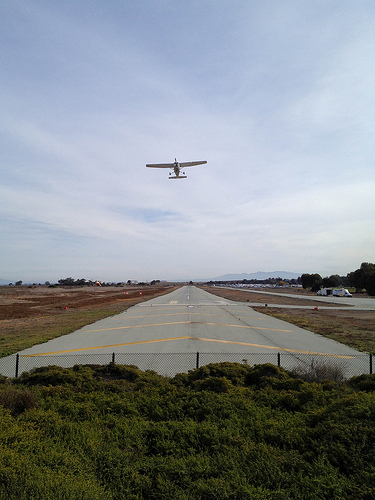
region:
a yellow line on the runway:
[17, 331, 358, 372]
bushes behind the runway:
[3, 363, 373, 499]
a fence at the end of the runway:
[1, 350, 369, 382]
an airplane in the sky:
[140, 155, 209, 182]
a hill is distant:
[202, 270, 308, 283]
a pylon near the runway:
[60, 303, 69, 311]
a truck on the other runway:
[331, 286, 354, 297]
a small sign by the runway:
[259, 301, 269, 307]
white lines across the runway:
[135, 296, 241, 307]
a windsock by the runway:
[91, 277, 102, 296]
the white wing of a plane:
[145, 160, 173, 171]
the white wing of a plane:
[178, 160, 204, 165]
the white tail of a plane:
[168, 173, 187, 180]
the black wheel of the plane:
[167, 169, 171, 174]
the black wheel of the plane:
[181, 169, 185, 177]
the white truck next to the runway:
[319, 285, 329, 296]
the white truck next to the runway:
[331, 287, 351, 296]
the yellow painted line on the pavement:
[19, 333, 347, 359]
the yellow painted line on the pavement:
[79, 319, 309, 337]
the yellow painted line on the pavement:
[105, 309, 273, 321]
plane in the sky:
[141, 152, 212, 184]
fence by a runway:
[23, 349, 353, 374]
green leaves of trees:
[10, 370, 364, 481]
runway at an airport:
[134, 277, 236, 352]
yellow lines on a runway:
[192, 316, 256, 353]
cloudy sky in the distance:
[33, 187, 323, 262]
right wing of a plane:
[181, 159, 209, 169]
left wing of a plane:
[144, 160, 171, 177]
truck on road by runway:
[320, 281, 357, 299]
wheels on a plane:
[169, 169, 186, 177]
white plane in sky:
[137, 148, 239, 211]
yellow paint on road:
[153, 325, 227, 359]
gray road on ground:
[177, 327, 227, 363]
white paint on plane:
[141, 148, 169, 176]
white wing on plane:
[137, 145, 166, 174]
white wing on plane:
[180, 152, 223, 186]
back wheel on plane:
[168, 168, 176, 179]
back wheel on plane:
[180, 165, 190, 174]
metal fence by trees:
[115, 336, 221, 412]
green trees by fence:
[125, 346, 295, 470]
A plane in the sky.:
[147, 159, 206, 180]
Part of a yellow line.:
[88, 340, 151, 349]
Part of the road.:
[99, 330, 148, 335]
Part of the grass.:
[16, 337, 33, 344]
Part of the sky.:
[93, 114, 133, 144]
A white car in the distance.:
[332, 287, 351, 297]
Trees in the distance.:
[58, 278, 85, 286]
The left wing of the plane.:
[145, 162, 173, 168]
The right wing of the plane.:
[180, 159, 207, 167]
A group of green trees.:
[302, 273, 321, 290]